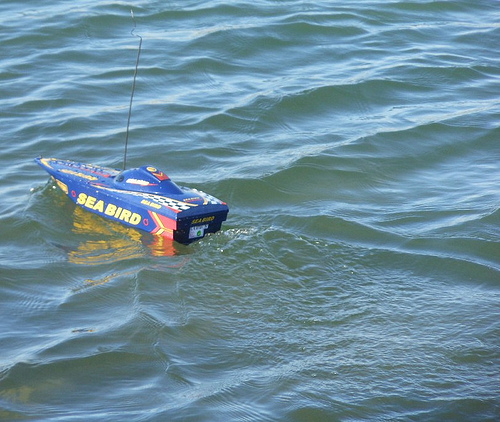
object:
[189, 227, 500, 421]
motion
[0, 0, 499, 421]
water's surface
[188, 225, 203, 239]
designs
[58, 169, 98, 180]
designs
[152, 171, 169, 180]
designs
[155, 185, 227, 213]
checkerboard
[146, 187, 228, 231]
corner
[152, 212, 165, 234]
arrow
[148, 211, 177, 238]
blocks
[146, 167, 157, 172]
figure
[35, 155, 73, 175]
boat tip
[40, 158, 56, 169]
curve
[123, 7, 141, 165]
antenna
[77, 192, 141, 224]
name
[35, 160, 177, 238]
side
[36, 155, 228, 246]
boat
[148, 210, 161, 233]
stripes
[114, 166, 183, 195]
engine room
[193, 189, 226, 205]
flags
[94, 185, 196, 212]
flags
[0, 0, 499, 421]
water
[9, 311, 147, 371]
waves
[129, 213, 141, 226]
letter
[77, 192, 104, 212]
words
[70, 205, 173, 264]
reflection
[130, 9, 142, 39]
tip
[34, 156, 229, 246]
shape